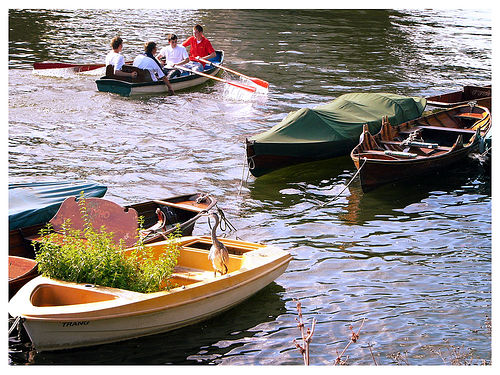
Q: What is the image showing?
A: It is showing a lake.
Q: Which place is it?
A: It is a lake.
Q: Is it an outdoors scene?
A: Yes, it is outdoors.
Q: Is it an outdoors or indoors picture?
A: It is outdoors.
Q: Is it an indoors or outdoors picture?
A: It is outdoors.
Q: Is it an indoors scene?
A: No, it is outdoors.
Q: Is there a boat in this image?
A: Yes, there is a boat.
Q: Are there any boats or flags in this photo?
A: Yes, there is a boat.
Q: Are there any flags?
A: No, there are no flags.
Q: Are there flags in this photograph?
A: No, there are no flags.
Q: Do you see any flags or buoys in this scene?
A: No, there are no flags or buoys.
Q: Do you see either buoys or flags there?
A: No, there are no flags or buoys.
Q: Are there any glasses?
A: No, there are no glasses.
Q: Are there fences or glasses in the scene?
A: No, there are no glasses or fences.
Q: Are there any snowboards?
A: No, there are no snowboards.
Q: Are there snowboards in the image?
A: No, there are no snowboards.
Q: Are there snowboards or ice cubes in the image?
A: No, there are no snowboards or ice cubes.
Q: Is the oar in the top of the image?
A: Yes, the oar is in the top of the image.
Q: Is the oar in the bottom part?
A: No, the oar is in the top of the image.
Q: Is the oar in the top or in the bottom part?
A: The oar is in the top of the image.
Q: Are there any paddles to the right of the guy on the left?
A: Yes, there is a paddle to the right of the guy.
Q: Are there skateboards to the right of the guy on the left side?
A: No, there is a paddle to the right of the guy.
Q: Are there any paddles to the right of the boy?
A: Yes, there is a paddle to the right of the boy.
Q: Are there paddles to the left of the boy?
A: No, the paddle is to the right of the boy.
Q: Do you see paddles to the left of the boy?
A: No, the paddle is to the right of the boy.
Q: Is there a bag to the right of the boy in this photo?
A: No, there is a paddle to the right of the boy.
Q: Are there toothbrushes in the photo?
A: No, there are no toothbrushes.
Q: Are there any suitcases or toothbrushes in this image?
A: No, there are no toothbrushes or suitcases.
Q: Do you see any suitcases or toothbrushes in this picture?
A: No, there are no toothbrushes or suitcases.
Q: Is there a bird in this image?
A: Yes, there is a bird.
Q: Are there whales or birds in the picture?
A: Yes, there is a bird.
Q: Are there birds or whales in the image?
A: Yes, there is a bird.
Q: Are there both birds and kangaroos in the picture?
A: No, there is a bird but no kangaroos.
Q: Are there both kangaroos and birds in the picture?
A: No, there is a bird but no kangaroos.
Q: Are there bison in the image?
A: No, there are no bison.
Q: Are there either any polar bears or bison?
A: No, there are no bison or polar bears.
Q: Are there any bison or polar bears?
A: No, there are no bison or polar bears.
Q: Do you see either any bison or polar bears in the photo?
A: No, there are no bison or polar bears.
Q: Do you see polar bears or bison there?
A: No, there are no bison or polar bears.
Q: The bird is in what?
A: The bird is in the boat.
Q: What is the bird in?
A: The bird is in the boat.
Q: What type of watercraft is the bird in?
A: The bird is in the boat.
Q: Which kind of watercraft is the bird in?
A: The bird is in the boat.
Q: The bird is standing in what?
A: The bird is standing in the boat.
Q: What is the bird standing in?
A: The bird is standing in the boat.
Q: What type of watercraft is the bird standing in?
A: The bird is standing in the boat.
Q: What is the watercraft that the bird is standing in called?
A: The watercraft is a boat.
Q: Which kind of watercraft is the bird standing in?
A: The bird is standing in the boat.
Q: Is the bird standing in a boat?
A: Yes, the bird is standing in a boat.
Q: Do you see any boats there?
A: Yes, there is a boat.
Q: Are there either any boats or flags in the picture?
A: Yes, there is a boat.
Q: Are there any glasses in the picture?
A: No, there are no glasses.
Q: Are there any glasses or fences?
A: No, there are no glasses or fences.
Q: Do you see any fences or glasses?
A: No, there are no glasses or fences.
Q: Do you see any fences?
A: No, there are no fences.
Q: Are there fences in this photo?
A: No, there are no fences.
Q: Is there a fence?
A: No, there are no fences.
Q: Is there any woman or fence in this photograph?
A: No, there are no fences or women.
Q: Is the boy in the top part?
A: Yes, the boy is in the top of the image.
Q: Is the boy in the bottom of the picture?
A: No, the boy is in the top of the image.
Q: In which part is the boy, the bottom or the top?
A: The boy is in the top of the image.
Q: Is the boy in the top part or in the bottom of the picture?
A: The boy is in the top of the image.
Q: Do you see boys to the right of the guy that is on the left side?
A: Yes, there is a boy to the right of the guy.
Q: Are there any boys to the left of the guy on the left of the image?
A: No, the boy is to the right of the guy.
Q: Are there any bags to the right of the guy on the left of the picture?
A: No, there is a boy to the right of the guy.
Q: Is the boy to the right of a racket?
A: No, the boy is to the right of a guy.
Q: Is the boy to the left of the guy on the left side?
A: No, the boy is to the right of the guy.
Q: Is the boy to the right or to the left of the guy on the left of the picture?
A: The boy is to the right of the guy.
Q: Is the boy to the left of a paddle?
A: Yes, the boy is to the left of a paddle.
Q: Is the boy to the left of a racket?
A: No, the boy is to the left of a paddle.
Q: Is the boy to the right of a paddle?
A: No, the boy is to the left of a paddle.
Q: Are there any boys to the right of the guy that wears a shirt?
A: Yes, there is a boy to the right of the guy.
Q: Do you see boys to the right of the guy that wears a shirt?
A: Yes, there is a boy to the right of the guy.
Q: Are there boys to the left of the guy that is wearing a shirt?
A: No, the boy is to the right of the guy.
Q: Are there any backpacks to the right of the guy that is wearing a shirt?
A: No, there is a boy to the right of the guy.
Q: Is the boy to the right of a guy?
A: Yes, the boy is to the right of a guy.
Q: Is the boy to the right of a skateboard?
A: No, the boy is to the right of a guy.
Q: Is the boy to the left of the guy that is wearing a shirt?
A: No, the boy is to the right of the guy.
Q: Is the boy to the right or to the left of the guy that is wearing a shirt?
A: The boy is to the right of the guy.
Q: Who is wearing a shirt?
A: The boy is wearing a shirt.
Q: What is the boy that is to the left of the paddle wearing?
A: The boy is wearing a shirt.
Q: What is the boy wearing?
A: The boy is wearing a shirt.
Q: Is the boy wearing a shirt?
A: Yes, the boy is wearing a shirt.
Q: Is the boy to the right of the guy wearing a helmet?
A: No, the boy is wearing a shirt.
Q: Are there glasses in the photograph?
A: No, there are no glasses.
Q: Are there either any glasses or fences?
A: No, there are no glasses or fences.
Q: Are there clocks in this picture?
A: No, there are no clocks.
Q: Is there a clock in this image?
A: No, there are no clocks.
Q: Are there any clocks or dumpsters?
A: No, there are no clocks or dumpsters.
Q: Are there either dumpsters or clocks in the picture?
A: No, there are no clocks or dumpsters.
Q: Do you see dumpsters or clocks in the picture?
A: No, there are no clocks or dumpsters.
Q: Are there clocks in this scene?
A: No, there are no clocks.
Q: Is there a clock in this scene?
A: No, there are no clocks.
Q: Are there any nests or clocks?
A: No, there are no clocks or nests.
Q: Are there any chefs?
A: No, there are no chefs.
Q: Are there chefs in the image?
A: No, there are no chefs.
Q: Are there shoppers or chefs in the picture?
A: No, there are no chefs or shoppers.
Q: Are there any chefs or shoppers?
A: No, there are no chefs or shoppers.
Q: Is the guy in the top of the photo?
A: Yes, the guy is in the top of the image.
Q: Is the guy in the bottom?
A: No, the guy is in the top of the image.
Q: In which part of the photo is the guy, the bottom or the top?
A: The guy is in the top of the image.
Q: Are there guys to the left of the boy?
A: Yes, there is a guy to the left of the boy.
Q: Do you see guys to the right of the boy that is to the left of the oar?
A: No, the guy is to the left of the boy.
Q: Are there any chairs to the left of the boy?
A: No, there is a guy to the left of the boy.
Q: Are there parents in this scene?
A: No, there are no parents.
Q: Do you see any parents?
A: No, there are no parents.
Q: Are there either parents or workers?
A: No, there are no parents or workers.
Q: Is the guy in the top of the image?
A: Yes, the guy is in the top of the image.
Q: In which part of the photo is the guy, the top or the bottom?
A: The guy is in the top of the image.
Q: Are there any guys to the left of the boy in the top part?
A: Yes, there is a guy to the left of the boy.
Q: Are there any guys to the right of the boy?
A: No, the guy is to the left of the boy.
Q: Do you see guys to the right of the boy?
A: No, the guy is to the left of the boy.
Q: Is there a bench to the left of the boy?
A: No, there is a guy to the left of the boy.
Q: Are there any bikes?
A: No, there are no bikes.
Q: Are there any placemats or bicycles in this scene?
A: No, there are no bicycles or placemats.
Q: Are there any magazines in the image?
A: No, there are no magazines.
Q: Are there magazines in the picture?
A: No, there are no magazines.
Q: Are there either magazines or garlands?
A: No, there are no magazines or garlands.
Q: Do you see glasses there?
A: No, there are no glasses.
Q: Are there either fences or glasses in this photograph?
A: No, there are no glasses or fences.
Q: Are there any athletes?
A: No, there are no athletes.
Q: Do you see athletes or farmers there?
A: No, there are no athletes or farmers.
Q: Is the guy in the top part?
A: Yes, the guy is in the top of the image.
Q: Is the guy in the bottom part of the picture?
A: No, the guy is in the top of the image.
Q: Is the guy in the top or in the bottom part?
A: The guy is in the top of the image.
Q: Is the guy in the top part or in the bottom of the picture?
A: The guy is in the top of the image.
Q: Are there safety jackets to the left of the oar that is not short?
A: No, there is a guy to the left of the oar.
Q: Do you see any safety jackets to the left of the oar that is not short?
A: No, there is a guy to the left of the oar.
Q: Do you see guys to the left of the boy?
A: Yes, there is a guy to the left of the boy.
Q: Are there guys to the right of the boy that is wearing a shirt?
A: No, the guy is to the left of the boy.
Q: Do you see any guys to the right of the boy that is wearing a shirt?
A: No, the guy is to the left of the boy.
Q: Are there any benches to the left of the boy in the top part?
A: No, there is a guy to the left of the boy.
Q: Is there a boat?
A: Yes, there is a boat.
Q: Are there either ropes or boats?
A: Yes, there is a boat.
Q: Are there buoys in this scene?
A: No, there are no buoys.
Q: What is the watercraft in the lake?
A: The watercraft is a boat.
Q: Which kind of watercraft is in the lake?
A: The watercraft is a boat.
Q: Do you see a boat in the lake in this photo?
A: Yes, there is a boat in the lake.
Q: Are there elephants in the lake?
A: No, there is a boat in the lake.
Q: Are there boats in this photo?
A: Yes, there is a boat.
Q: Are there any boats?
A: Yes, there is a boat.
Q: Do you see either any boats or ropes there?
A: Yes, there is a boat.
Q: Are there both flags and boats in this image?
A: No, there is a boat but no flags.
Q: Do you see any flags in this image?
A: No, there are no flags.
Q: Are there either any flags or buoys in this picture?
A: No, there are no flags or buoys.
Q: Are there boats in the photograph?
A: Yes, there is a boat.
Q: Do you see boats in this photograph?
A: Yes, there is a boat.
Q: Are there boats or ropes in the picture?
A: Yes, there is a boat.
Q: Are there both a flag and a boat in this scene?
A: No, there is a boat but no flags.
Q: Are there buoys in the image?
A: No, there are no buoys.